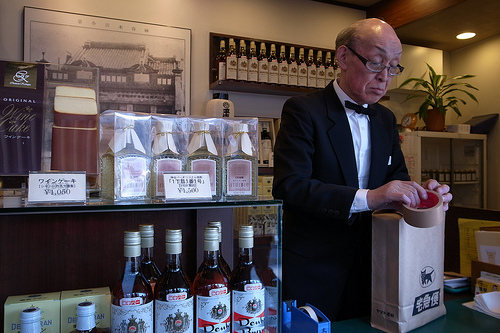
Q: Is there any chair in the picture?
A: No, there are no chairs.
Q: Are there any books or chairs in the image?
A: No, there are no chairs or books.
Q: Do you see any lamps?
A: No, there are no lamps.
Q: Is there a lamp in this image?
A: No, there are no lamps.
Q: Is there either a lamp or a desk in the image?
A: No, there are no lamps or desks.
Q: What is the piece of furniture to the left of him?
A: The piece of furniture is a shelf.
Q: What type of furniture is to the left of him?
A: The piece of furniture is a shelf.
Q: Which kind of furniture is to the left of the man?
A: The piece of furniture is a shelf.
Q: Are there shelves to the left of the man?
A: Yes, there is a shelf to the left of the man.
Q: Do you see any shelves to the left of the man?
A: Yes, there is a shelf to the left of the man.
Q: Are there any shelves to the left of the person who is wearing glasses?
A: Yes, there is a shelf to the left of the man.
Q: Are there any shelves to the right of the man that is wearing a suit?
A: No, the shelf is to the left of the man.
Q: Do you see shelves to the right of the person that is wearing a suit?
A: No, the shelf is to the left of the man.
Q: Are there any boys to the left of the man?
A: No, there is a shelf to the left of the man.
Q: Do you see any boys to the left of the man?
A: No, there is a shelf to the left of the man.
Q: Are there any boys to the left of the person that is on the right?
A: No, there is a shelf to the left of the man.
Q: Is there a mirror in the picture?
A: No, there are no mirrors.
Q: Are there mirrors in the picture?
A: No, there are no mirrors.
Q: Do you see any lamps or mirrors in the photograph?
A: No, there are no mirrors or lamps.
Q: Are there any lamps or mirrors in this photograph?
A: No, there are no mirrors or lamps.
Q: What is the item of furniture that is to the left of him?
A: The piece of furniture is a shelf.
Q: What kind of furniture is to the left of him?
A: The piece of furniture is a shelf.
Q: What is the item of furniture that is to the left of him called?
A: The piece of furniture is a shelf.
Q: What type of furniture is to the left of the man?
A: The piece of furniture is a shelf.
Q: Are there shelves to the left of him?
A: Yes, there is a shelf to the left of the man.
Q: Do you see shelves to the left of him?
A: Yes, there is a shelf to the left of the man.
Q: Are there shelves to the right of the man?
A: No, the shelf is to the left of the man.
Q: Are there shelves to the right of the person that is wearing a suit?
A: No, the shelf is to the left of the man.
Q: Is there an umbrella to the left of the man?
A: No, there is a shelf to the left of the man.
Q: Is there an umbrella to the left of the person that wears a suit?
A: No, there is a shelf to the left of the man.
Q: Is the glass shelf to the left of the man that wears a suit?
A: Yes, the shelf is to the left of the man.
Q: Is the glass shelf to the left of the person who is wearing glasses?
A: Yes, the shelf is to the left of the man.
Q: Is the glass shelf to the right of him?
A: No, the shelf is to the left of the man.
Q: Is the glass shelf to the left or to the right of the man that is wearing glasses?
A: The shelf is to the left of the man.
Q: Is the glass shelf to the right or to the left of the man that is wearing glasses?
A: The shelf is to the left of the man.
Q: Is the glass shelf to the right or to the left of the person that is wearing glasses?
A: The shelf is to the left of the man.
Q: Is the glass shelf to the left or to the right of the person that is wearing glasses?
A: The shelf is to the left of the man.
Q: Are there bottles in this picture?
A: Yes, there is a bottle.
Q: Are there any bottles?
A: Yes, there is a bottle.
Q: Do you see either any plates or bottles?
A: Yes, there is a bottle.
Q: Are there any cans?
A: No, there are no cans.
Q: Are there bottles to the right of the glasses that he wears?
A: No, the bottle is to the left of the glasses.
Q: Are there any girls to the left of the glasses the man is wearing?
A: No, there is a bottle to the left of the glasses.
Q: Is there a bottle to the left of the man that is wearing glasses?
A: Yes, there is a bottle to the left of the man.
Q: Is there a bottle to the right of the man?
A: No, the bottle is to the left of the man.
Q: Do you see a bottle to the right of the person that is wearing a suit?
A: No, the bottle is to the left of the man.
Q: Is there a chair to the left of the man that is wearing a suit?
A: No, there is a bottle to the left of the man.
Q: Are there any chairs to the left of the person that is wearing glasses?
A: No, there is a bottle to the left of the man.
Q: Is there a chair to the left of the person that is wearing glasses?
A: No, there is a bottle to the left of the man.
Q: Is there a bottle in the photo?
A: Yes, there is a bottle.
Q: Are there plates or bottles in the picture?
A: Yes, there is a bottle.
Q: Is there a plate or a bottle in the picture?
A: Yes, there is a bottle.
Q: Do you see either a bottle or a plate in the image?
A: Yes, there is a bottle.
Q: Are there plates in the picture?
A: No, there are no plates.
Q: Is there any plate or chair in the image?
A: No, there are no plates or chairs.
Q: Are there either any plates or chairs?
A: No, there are no plates or chairs.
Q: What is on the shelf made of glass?
A: The bottle is on the shelf.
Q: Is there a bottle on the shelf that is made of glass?
A: Yes, there is a bottle on the shelf.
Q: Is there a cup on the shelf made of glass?
A: No, there is a bottle on the shelf.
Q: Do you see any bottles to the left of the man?
A: Yes, there is a bottle to the left of the man.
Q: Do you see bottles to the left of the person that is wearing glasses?
A: Yes, there is a bottle to the left of the man.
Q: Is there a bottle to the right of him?
A: No, the bottle is to the left of the man.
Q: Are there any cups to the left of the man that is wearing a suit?
A: No, there is a bottle to the left of the man.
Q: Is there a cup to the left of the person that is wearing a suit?
A: No, there is a bottle to the left of the man.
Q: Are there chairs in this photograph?
A: No, there are no chairs.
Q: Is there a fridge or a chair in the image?
A: No, there are no chairs or refrigerators.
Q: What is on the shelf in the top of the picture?
A: The bottles are on the shelf.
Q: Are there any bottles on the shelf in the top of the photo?
A: Yes, there are bottles on the shelf.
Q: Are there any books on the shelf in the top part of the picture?
A: No, there are bottles on the shelf.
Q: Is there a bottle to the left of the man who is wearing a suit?
A: Yes, there are bottles to the left of the man.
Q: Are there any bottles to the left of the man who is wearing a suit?
A: Yes, there are bottles to the left of the man.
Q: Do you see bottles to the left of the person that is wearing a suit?
A: Yes, there are bottles to the left of the man.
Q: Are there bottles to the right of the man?
A: No, the bottles are to the left of the man.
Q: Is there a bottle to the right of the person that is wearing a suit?
A: No, the bottles are to the left of the man.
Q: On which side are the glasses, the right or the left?
A: The glasses are on the right of the image.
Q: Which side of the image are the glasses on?
A: The glasses are on the right of the image.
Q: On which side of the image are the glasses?
A: The glasses are on the right of the image.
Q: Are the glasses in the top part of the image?
A: Yes, the glasses are in the top of the image.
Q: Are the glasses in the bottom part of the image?
A: No, the glasses are in the top of the image.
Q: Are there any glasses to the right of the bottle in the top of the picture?
A: Yes, there are glasses to the right of the bottle.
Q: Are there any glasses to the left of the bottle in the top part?
A: No, the glasses are to the right of the bottle.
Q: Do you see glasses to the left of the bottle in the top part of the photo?
A: No, the glasses are to the right of the bottle.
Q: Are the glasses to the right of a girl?
A: No, the glasses are to the right of a bottle.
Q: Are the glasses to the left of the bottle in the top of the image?
A: No, the glasses are to the right of the bottle.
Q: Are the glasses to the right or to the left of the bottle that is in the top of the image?
A: The glasses are to the right of the bottle.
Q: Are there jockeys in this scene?
A: No, there are no jockeys.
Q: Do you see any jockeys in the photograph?
A: No, there are no jockeys.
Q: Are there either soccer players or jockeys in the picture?
A: No, there are no jockeys or soccer players.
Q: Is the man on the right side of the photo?
A: Yes, the man is on the right of the image.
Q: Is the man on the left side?
A: No, the man is on the right of the image.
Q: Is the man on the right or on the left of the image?
A: The man is on the right of the image.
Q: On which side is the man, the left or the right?
A: The man is on the right of the image.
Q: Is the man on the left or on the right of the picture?
A: The man is on the right of the image.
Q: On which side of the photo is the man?
A: The man is on the right of the image.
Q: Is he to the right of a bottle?
A: Yes, the man is to the right of a bottle.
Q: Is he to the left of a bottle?
A: No, the man is to the right of a bottle.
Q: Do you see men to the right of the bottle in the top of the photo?
A: Yes, there is a man to the right of the bottle.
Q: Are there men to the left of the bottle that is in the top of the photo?
A: No, the man is to the right of the bottle.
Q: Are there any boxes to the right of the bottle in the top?
A: No, there is a man to the right of the bottle.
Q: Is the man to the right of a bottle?
A: Yes, the man is to the right of a bottle.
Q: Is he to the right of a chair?
A: No, the man is to the right of a bottle.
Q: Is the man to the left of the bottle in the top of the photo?
A: No, the man is to the right of the bottle.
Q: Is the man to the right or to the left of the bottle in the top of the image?
A: The man is to the right of the bottle.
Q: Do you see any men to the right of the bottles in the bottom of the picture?
A: Yes, there is a man to the right of the bottles.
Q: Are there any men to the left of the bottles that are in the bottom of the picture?
A: No, the man is to the right of the bottles.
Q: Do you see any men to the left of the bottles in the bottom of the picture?
A: No, the man is to the right of the bottles.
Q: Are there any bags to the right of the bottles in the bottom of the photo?
A: No, there is a man to the right of the bottles.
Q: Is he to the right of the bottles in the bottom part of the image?
A: Yes, the man is to the right of the bottles.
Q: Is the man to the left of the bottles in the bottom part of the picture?
A: No, the man is to the right of the bottles.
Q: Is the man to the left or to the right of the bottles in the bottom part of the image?
A: The man is to the right of the bottles.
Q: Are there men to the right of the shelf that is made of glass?
A: Yes, there is a man to the right of the shelf.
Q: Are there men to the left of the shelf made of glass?
A: No, the man is to the right of the shelf.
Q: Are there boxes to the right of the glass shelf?
A: No, there is a man to the right of the shelf.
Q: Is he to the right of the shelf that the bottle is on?
A: Yes, the man is to the right of the shelf.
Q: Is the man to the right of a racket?
A: No, the man is to the right of the shelf.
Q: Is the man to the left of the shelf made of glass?
A: No, the man is to the right of the shelf.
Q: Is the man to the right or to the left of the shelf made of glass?
A: The man is to the right of the shelf.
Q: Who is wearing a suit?
A: The man is wearing a suit.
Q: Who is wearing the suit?
A: The man is wearing a suit.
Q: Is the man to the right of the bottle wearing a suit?
A: Yes, the man is wearing a suit.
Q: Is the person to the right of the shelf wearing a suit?
A: Yes, the man is wearing a suit.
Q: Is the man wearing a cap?
A: No, the man is wearing a suit.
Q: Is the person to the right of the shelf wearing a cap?
A: No, the man is wearing a suit.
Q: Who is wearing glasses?
A: The man is wearing glasses.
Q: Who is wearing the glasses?
A: The man is wearing glasses.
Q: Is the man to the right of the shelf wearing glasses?
A: Yes, the man is wearing glasses.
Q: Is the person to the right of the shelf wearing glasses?
A: Yes, the man is wearing glasses.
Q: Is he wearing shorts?
A: No, the man is wearing glasses.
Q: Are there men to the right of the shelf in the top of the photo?
A: Yes, there is a man to the right of the shelf.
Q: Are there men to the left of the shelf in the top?
A: No, the man is to the right of the shelf.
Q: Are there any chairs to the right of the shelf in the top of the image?
A: No, there is a man to the right of the shelf.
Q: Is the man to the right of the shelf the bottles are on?
A: Yes, the man is to the right of the shelf.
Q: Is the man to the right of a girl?
A: No, the man is to the right of the shelf.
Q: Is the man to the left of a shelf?
A: No, the man is to the right of a shelf.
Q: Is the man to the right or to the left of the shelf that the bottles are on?
A: The man is to the right of the shelf.